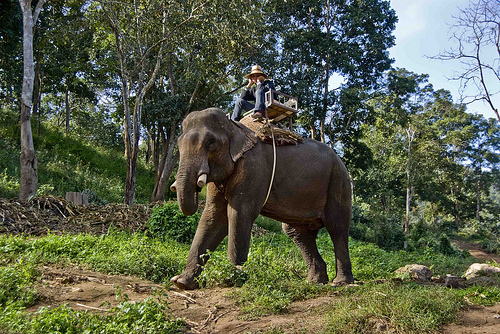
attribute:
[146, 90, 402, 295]
elephant — large, gray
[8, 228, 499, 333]
dirt path — rocky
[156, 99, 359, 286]
elephant — white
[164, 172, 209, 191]
tusk — short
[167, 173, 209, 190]
tusks — cut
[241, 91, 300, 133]
seat — wooden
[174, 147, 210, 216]
trunk — curled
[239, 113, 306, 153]
blanket — folded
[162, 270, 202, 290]
foot — large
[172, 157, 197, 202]
trunk — curled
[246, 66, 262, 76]
hat — tan